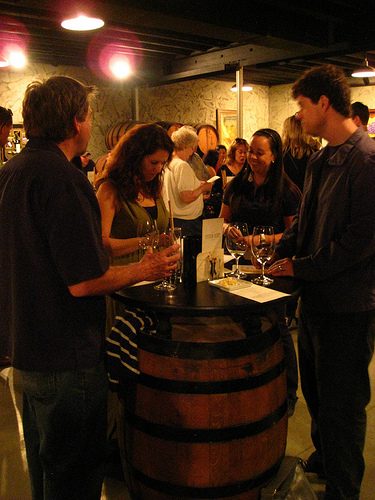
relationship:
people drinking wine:
[23, 49, 366, 273] [158, 193, 193, 284]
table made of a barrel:
[121, 270, 306, 318] [113, 322, 309, 496]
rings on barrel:
[149, 370, 261, 398] [113, 322, 309, 496]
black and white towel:
[115, 360, 127, 372] [113, 312, 137, 333]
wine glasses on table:
[228, 217, 278, 281] [121, 270, 306, 318]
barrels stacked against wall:
[105, 114, 226, 155] [125, 86, 217, 118]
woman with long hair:
[102, 127, 205, 405] [109, 117, 174, 204]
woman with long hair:
[102, 127, 205, 405] [109, 162, 138, 204]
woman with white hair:
[102, 127, 205, 405] [175, 129, 197, 146]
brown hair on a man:
[299, 69, 353, 101] [271, 51, 372, 362]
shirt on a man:
[297, 134, 366, 274] [271, 51, 372, 362]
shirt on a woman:
[297, 134, 366, 274] [102, 127, 205, 405]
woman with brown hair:
[102, 127, 205, 405] [299, 69, 353, 101]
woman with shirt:
[102, 127, 205, 405] [297, 134, 366, 274]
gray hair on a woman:
[186, 123, 197, 142] [102, 127, 205, 405]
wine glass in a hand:
[133, 221, 164, 263] [136, 253, 188, 274]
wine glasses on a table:
[228, 217, 278, 281] [121, 270, 306, 318]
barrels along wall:
[105, 114, 226, 155] [125, 86, 217, 118]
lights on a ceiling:
[64, 17, 104, 38] [160, 16, 297, 74]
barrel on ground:
[113, 322, 309, 496] [291, 423, 319, 468]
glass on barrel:
[226, 220, 249, 278] [113, 322, 309, 496]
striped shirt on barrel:
[93, 308, 155, 391] [113, 322, 309, 496]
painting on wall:
[210, 101, 254, 148] [125, 86, 217, 118]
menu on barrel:
[207, 271, 297, 307] [113, 322, 309, 496]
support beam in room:
[233, 64, 249, 142] [2, 1, 373, 165]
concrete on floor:
[3, 411, 28, 490] [290, 419, 311, 453]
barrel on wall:
[113, 322, 309, 496] [125, 86, 217, 118]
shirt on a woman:
[115, 187, 177, 249] [102, 127, 205, 405]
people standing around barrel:
[23, 49, 366, 273] [113, 322, 309, 496]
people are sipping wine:
[23, 49, 366, 273] [158, 193, 193, 284]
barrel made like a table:
[113, 322, 309, 496] [121, 270, 306, 318]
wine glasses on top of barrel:
[228, 217, 278, 281] [113, 322, 309, 496]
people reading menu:
[165, 124, 204, 224] [204, 169, 225, 187]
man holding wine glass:
[14, 75, 125, 352] [133, 221, 164, 263]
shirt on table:
[297, 134, 366, 274] [121, 270, 306, 318]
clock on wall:
[110, 56, 143, 101] [125, 86, 217, 118]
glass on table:
[226, 220, 249, 278] [121, 270, 306, 318]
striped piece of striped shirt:
[105, 307, 149, 377] [102, 308, 155, 385]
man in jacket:
[271, 51, 372, 362] [297, 134, 366, 274]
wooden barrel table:
[147, 395, 274, 436] [121, 270, 306, 318]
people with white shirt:
[165, 124, 204, 224] [171, 160, 204, 221]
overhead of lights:
[43, 55, 90, 79] [56, 9, 103, 38]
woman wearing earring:
[228, 121, 302, 256] [268, 156, 280, 168]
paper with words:
[197, 221, 233, 266] [207, 231, 224, 242]